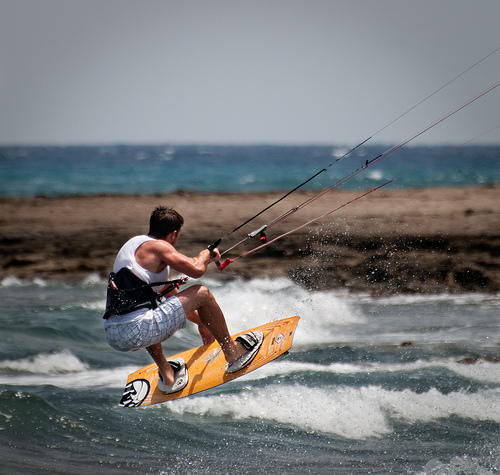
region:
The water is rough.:
[0, 274, 499, 473]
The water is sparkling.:
[0, 282, 498, 474]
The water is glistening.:
[2, 282, 499, 473]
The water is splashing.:
[2, 286, 497, 473]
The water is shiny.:
[1, 289, 498, 473]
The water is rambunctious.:
[0, 287, 497, 473]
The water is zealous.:
[1, 288, 497, 473]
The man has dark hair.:
[101, 192, 271, 400]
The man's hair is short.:
[86, 183, 278, 415]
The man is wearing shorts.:
[83, 203, 323, 415]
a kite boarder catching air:
[103, 206, 301, 406]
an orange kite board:
[121, 316, 301, 408]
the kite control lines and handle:
[207, 78, 498, 270]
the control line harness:
[103, 267, 187, 317]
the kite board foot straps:
[225, 326, 262, 372]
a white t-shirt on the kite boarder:
[113, 235, 171, 287]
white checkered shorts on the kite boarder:
[106, 296, 186, 353]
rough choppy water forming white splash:
[301, 283, 499, 473]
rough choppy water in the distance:
[1, 143, 499, 190]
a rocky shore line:
[252, 191, 498, 298]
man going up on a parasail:
[86, 188, 311, 438]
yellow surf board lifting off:
[119, 319, 309, 392]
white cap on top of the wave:
[268, 379, 436, 451]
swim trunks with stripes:
[99, 311, 196, 350]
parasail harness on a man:
[99, 269, 171, 316]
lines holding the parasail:
[225, 111, 444, 259]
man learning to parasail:
[84, 154, 361, 439]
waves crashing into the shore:
[302, 243, 441, 328]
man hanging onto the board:
[184, 306, 234, 406]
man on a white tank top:
[99, 200, 197, 315]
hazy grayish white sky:
[87, 57, 371, 125]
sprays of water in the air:
[223, 390, 465, 473]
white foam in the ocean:
[291, 391, 371, 421]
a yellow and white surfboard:
[119, 316, 307, 407]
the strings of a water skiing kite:
[184, 102, 498, 245]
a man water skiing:
[70, 181, 297, 418]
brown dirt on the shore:
[145, 185, 482, 281]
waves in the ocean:
[319, 332, 496, 462]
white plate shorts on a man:
[89, 305, 219, 342]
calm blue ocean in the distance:
[37, 130, 302, 190]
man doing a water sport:
[88, 203, 337, 421]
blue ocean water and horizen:
[10, 121, 287, 171]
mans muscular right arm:
[128, 228, 213, 283]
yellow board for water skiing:
[85, 322, 342, 409]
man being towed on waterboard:
[84, 183, 404, 449]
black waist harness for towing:
[86, 194, 296, 354]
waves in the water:
[330, 266, 490, 463]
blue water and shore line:
[8, 170, 272, 206]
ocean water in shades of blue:
[5, 119, 290, 186]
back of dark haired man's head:
[136, 196, 191, 257]